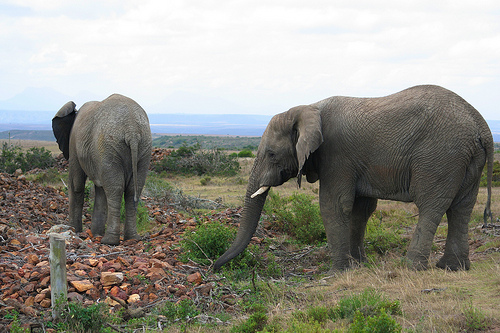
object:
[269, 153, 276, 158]
eye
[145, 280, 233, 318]
twigs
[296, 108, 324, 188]
ear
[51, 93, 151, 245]
elephant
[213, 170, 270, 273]
trunk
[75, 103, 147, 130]
floor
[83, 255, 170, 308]
bricks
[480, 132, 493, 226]
tail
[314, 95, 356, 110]
bump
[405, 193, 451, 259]
leg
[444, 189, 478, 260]
leg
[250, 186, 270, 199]
left tusk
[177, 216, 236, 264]
bush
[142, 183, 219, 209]
brush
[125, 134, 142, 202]
elephant's tail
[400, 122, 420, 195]
wrinkles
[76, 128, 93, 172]
wrinkles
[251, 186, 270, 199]
tuck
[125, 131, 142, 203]
tail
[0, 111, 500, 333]
ground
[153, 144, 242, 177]
foilage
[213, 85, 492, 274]
elephant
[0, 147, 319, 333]
rocks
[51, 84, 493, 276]
elephants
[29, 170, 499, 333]
grass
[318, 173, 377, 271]
legs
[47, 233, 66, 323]
post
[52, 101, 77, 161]
ear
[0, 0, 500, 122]
sky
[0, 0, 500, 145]
background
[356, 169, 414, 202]
elephant's stomach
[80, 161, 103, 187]
elephant's stomach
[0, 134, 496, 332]
field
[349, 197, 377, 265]
leg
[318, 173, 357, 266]
leg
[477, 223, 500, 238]
pile